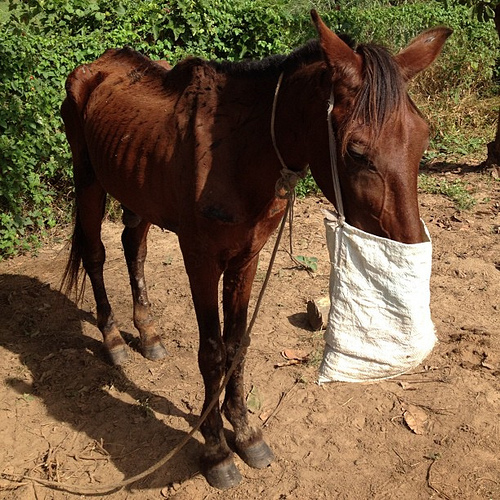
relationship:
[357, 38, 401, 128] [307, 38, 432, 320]
hair on head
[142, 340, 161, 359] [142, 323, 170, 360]
hoof on foot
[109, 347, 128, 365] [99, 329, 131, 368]
hoof on foot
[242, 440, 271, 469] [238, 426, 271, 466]
hoof on foot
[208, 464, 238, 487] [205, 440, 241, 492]
hoof on foot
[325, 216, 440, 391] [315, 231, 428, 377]
bag for feed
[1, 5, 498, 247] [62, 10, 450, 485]
foliage behind animal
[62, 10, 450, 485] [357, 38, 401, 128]
horse have hair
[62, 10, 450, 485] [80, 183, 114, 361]
horse have leg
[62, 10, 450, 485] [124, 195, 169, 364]
horse have leg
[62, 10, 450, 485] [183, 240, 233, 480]
horse have leg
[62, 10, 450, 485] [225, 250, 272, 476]
horse have leg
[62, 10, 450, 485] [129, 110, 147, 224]
horse have ribs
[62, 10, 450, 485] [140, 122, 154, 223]
horse have ribs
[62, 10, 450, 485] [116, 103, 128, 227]
horse have ribs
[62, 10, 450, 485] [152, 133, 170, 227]
horse have ribs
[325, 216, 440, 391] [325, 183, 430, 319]
bag on muzzle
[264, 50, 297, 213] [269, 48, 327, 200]
rope on neck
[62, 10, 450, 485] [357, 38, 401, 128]
horse have mane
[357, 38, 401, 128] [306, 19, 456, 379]
mane on front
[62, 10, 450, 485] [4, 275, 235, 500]
horse have shadow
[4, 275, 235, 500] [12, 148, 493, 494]
shadow on ground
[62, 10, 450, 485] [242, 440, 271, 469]
horse have hoof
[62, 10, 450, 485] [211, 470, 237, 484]
horse have hoof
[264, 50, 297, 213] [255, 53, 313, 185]
rope on neck